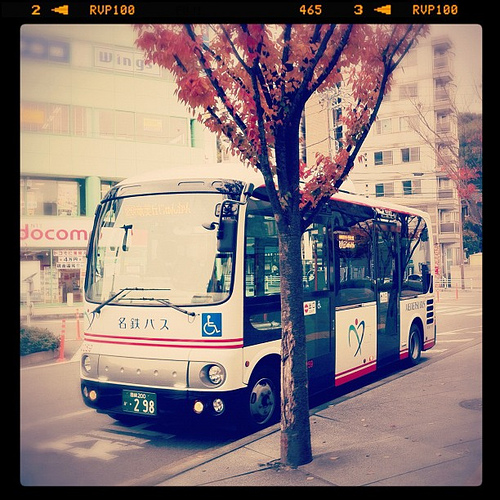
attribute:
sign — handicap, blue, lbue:
[201, 314, 220, 337]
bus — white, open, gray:
[78, 176, 436, 432]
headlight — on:
[206, 364, 223, 385]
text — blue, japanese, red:
[115, 318, 172, 330]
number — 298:
[133, 398, 155, 415]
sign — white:
[20, 216, 95, 248]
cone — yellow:
[57, 314, 67, 355]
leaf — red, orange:
[361, 40, 373, 58]